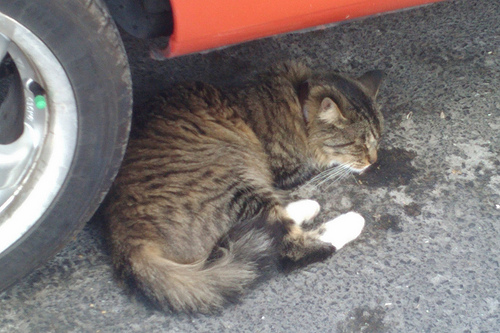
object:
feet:
[315, 212, 365, 250]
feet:
[285, 199, 320, 225]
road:
[0, 4, 497, 330]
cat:
[102, 59, 386, 316]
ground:
[6, 0, 500, 333]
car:
[0, 0, 439, 290]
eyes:
[320, 139, 355, 149]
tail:
[126, 229, 276, 315]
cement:
[423, 107, 489, 232]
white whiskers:
[298, 161, 357, 194]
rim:
[1, 12, 78, 254]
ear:
[318, 96, 349, 129]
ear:
[358, 70, 384, 102]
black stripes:
[167, 156, 235, 218]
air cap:
[34, 95, 47, 110]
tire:
[0, 0, 132, 295]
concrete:
[11, 24, 496, 324]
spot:
[357, 128, 417, 191]